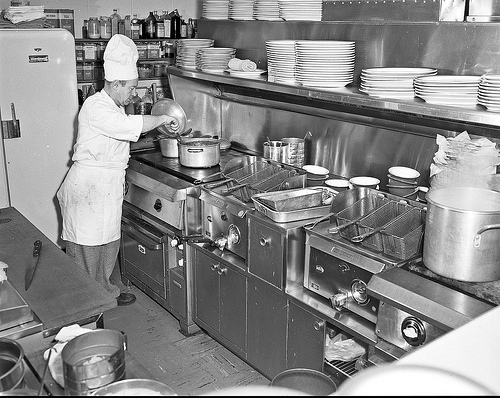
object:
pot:
[176, 136, 221, 169]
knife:
[24, 239, 44, 291]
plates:
[296, 41, 355, 45]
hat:
[102, 33, 139, 81]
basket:
[379, 208, 423, 260]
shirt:
[69, 89, 144, 168]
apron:
[55, 162, 126, 246]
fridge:
[0, 27, 76, 249]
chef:
[55, 33, 181, 307]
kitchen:
[1, 0, 498, 398]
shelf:
[146, 58, 499, 136]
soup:
[180, 140, 218, 144]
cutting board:
[0, 206, 118, 330]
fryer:
[355, 198, 412, 250]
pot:
[424, 185, 499, 283]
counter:
[409, 258, 498, 305]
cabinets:
[189, 243, 326, 381]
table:
[0, 203, 120, 354]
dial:
[154, 199, 162, 213]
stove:
[117, 141, 261, 336]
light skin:
[105, 80, 138, 107]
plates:
[361, 67, 437, 75]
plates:
[413, 76, 483, 84]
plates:
[196, 47, 236, 51]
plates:
[177, 39, 215, 41]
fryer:
[246, 167, 306, 204]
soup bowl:
[388, 165, 422, 184]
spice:
[87, 17, 101, 40]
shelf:
[75, 38, 197, 42]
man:
[54, 32, 180, 307]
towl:
[228, 57, 257, 72]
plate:
[224, 68, 267, 76]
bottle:
[146, 11, 157, 39]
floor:
[128, 325, 216, 390]